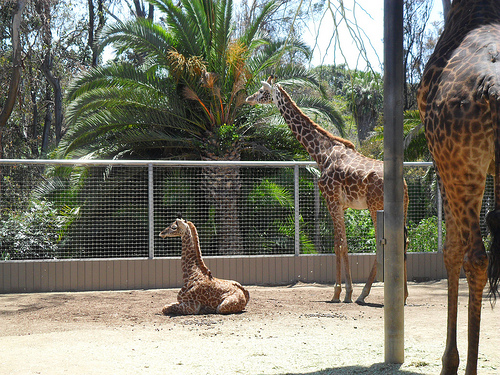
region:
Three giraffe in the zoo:
[184, 69, 481, 330]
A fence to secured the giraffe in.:
[37, 148, 354, 253]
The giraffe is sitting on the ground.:
[159, 213, 262, 333]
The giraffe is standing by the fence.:
[250, 82, 393, 279]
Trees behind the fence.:
[47, 25, 296, 232]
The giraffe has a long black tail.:
[481, 140, 498, 256]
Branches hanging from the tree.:
[293, 12, 385, 78]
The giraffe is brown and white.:
[148, 211, 246, 327]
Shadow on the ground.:
[331, 351, 386, 373]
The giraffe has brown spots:
[432, 38, 482, 153]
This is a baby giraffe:
[177, 214, 312, 308]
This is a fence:
[109, 140, 364, 267]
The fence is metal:
[208, 144, 278, 250]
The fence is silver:
[201, 187, 309, 277]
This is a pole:
[316, 256, 486, 298]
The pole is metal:
[376, 241, 407, 312]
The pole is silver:
[363, 299, 415, 372]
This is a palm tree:
[134, 50, 224, 147]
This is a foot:
[459, 299, 493, 324]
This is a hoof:
[324, 281, 351, 307]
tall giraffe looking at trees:
[239, 76, 419, 311]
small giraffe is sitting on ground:
[148, 213, 256, 328]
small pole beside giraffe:
[375, 24, 415, 369]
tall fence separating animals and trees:
[1, 153, 497, 293]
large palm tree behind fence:
[43, 2, 350, 263]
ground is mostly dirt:
[4, 267, 496, 372]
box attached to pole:
[368, 205, 392, 286]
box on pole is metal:
[367, 207, 392, 289]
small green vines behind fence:
[342, 198, 446, 261]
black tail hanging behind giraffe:
[481, 198, 498, 310]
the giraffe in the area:
[147, 210, 262, 340]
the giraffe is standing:
[240, 68, 417, 321]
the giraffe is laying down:
[150, 213, 260, 328]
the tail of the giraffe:
[475, 152, 499, 302]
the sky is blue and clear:
[357, 5, 382, 62]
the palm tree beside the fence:
[45, 13, 385, 160]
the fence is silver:
[0, 165, 487, 273]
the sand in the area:
[13, 299, 135, 373]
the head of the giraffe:
[158, 214, 194, 239]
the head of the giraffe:
[230, 72, 293, 114]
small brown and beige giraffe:
[155, 195, 260, 333]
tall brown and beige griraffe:
[246, 67, 378, 305]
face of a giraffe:
[151, 215, 196, 247]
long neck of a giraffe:
[280, 93, 311, 154]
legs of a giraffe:
[327, 195, 355, 310]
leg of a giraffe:
[441, 221, 459, 371]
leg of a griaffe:
[457, 250, 490, 371]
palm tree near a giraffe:
[73, 48, 248, 148]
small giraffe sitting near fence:
[141, 208, 253, 330]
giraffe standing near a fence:
[237, 73, 368, 253]